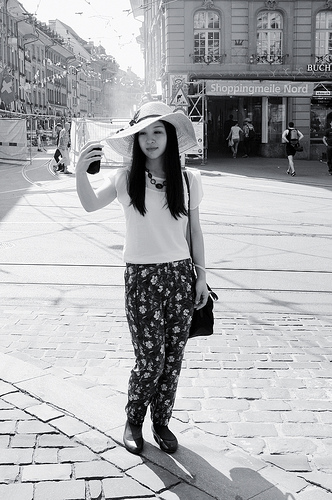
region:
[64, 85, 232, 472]
woman taking selfie outdoors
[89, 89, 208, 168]
woman wearing big floppy hat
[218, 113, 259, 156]
people entering shopping store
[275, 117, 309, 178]
person carrying a backpack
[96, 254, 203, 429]
woman wearing flowered pants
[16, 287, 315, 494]
standing on brick plaza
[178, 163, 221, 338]
woman holding shoulder purse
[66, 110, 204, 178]
sheets hanging on lines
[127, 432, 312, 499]
shadow of woman on bricks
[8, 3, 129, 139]
row of buildings along street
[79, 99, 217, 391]
girl on side of road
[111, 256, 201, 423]
pants with flowered print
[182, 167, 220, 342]
bag on woman's shoulder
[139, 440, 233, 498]
shadow of woman on cobblestone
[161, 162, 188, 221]
long dark hair on blouse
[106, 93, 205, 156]
hat with wide floppy brim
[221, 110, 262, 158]
people walking into building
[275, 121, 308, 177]
person wearing backpack and shorts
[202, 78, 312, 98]
sign above open doorway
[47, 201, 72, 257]
shadows of wires on street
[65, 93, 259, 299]
Girl posing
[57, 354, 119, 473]
Cobble stone streets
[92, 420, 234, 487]
Girls shoes on the curb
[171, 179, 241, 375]
Girl's handbag on her shoulder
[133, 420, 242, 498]
Girl's shadow on the street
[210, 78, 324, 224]
People shopping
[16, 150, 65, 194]
Trolley tracks on the street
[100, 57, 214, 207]
Lady wearing a hat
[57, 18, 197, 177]
Main street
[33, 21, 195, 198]
Woman with a necklace on the street corner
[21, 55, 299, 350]
a woman taking a selfie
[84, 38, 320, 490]
a tourist in the city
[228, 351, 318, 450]
a street made of bricks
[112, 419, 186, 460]
a pair of leather shoes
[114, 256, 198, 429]
a pair of flowery pants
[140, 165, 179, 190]
a bulky necklace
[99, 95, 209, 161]
a large straw hat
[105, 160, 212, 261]
a feminine white blouse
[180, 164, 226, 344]
bag with a long strap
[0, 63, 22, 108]
a large flag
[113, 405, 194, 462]
shoes are black and dull